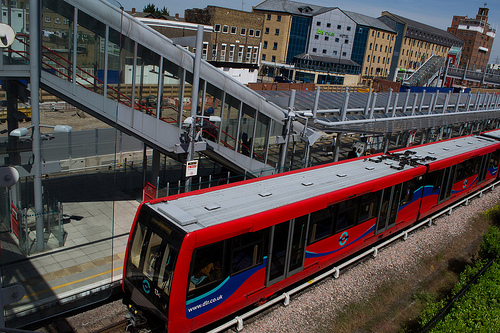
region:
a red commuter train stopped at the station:
[119, 124, 497, 331]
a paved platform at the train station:
[0, 121, 496, 315]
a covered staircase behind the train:
[1, 0, 336, 177]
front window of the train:
[128, 220, 177, 294]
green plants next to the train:
[414, 200, 499, 331]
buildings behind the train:
[1, 0, 498, 87]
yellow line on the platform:
[2, 265, 122, 303]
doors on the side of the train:
[266, 156, 490, 283]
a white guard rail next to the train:
[193, 179, 498, 331]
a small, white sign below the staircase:
[185, 159, 200, 178]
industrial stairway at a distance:
[392, 44, 456, 95]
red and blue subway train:
[112, 121, 499, 331]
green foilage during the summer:
[401, 267, 494, 332]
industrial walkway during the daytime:
[8, 3, 295, 185]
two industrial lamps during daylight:
[2, 94, 87, 162]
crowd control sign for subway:
[173, 155, 208, 178]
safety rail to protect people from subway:
[180, 196, 480, 331]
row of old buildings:
[147, 3, 498, 96]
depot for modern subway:
[222, 69, 499, 174]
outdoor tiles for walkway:
[68, 204, 114, 261]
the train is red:
[84, 164, 331, 329]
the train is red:
[314, 168, 439, 250]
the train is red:
[272, 214, 400, 281]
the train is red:
[374, 157, 480, 262]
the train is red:
[167, 207, 306, 307]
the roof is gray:
[269, 72, 437, 145]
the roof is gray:
[189, 169, 274, 224]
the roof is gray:
[414, 79, 499, 114]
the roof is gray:
[137, 19, 246, 109]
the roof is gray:
[347, 12, 417, 54]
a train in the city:
[12, 14, 472, 313]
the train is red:
[94, 86, 495, 308]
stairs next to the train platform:
[8, 2, 312, 177]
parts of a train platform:
[240, 61, 499, 133]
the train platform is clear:
[5, 159, 141, 286]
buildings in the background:
[180, 2, 495, 102]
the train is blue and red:
[174, 233, 379, 307]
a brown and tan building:
[260, 1, 402, 85]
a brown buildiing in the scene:
[448, 1, 498, 83]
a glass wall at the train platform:
[6, 8, 121, 304]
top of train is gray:
[106, 128, 496, 222]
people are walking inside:
[178, 101, 283, 177]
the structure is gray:
[0, 4, 307, 181]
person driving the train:
[176, 256, 225, 301]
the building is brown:
[197, 0, 270, 71]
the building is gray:
[308, 1, 358, 72]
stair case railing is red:
[9, 28, 141, 112]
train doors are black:
[261, 206, 306, 281]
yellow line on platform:
[1, 262, 141, 300]